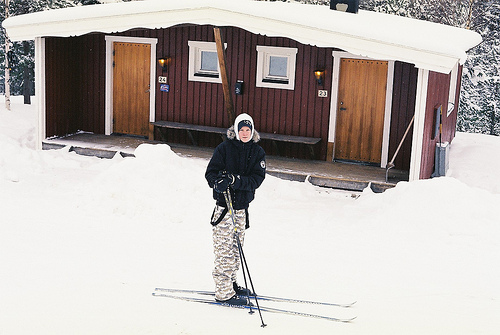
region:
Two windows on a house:
[180, 31, 300, 91]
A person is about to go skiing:
[141, 101, 366, 328]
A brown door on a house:
[100, 25, 165, 140]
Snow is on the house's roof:
[0, 0, 482, 76]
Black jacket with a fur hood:
[200, 117, 266, 209]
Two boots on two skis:
[145, 276, 361, 327]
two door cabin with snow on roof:
[3, 0, 482, 191]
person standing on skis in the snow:
[152, 112, 355, 323]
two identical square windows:
[186, 40, 296, 90]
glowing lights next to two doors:
[103, 35, 389, 171]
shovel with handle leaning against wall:
[380, 117, 415, 182]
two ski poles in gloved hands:
[216, 169, 265, 329]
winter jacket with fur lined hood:
[203, 123, 265, 208]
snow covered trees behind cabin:
[0, 0, 498, 137]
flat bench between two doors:
[102, 33, 393, 165]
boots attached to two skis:
[153, 283, 358, 321]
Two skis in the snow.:
[151, 285, 360, 325]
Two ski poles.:
[218, 173, 267, 328]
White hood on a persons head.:
[235, 112, 255, 144]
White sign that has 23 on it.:
[316, 89, 328, 99]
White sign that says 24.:
[156, 74, 166, 83]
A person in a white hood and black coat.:
[206, 112, 268, 304]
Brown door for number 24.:
[109, 38, 152, 137]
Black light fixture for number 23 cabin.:
[311, 65, 327, 87]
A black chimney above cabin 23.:
[330, 0, 360, 15]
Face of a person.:
[237, 125, 250, 142]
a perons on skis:
[202, 73, 402, 330]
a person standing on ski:
[160, 123, 367, 332]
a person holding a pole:
[202, 180, 289, 316]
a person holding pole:
[207, 197, 271, 330]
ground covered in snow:
[96, 224, 156, 326]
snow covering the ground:
[55, 243, 112, 318]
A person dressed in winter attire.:
[200, 110, 257, 312]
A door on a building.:
[330, 61, 390, 167]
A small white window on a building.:
[254, 47, 302, 92]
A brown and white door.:
[104, 36, 159, 141]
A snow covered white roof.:
[3, 1, 480, 75]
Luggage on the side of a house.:
[422, 101, 461, 178]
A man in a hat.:
[230, 111, 262, 144]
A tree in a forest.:
[4, 0, 12, 103]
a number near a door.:
[316, 86, 328, 99]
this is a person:
[125, 59, 443, 281]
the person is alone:
[170, 87, 381, 280]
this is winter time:
[63, 55, 364, 239]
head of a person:
[234, 114, 251, 141]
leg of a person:
[210, 207, 234, 299]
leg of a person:
[232, 210, 243, 267]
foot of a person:
[218, 293, 246, 308]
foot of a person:
[231, 283, 253, 293]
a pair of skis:
[154, 284, 358, 323]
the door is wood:
[335, 57, 381, 161]